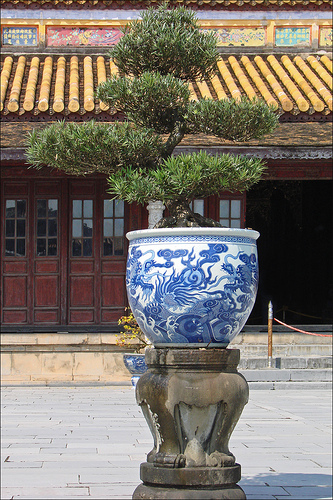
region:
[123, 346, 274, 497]
weathered and chipped pedestal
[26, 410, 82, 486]
staggered brick walk way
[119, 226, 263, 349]
blue and white flower planter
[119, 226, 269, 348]
flower planter with Asian motif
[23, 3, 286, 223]
bonsai plant in a planter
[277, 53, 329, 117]
bamboo sticks on the roof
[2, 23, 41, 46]
blue and gold decoration on roof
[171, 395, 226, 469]
chipped off portion of pedastal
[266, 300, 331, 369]
velvet rope and stand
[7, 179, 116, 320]
sliding wooden walls with many windows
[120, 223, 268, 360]
A blue and white vase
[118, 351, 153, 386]
A blue and white vase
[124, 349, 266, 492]
A stone stand for the vase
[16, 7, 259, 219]
a bonsai tree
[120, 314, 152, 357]
A plant in the vase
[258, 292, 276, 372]
A wooden rod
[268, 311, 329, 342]
A velvet rope blocking entrance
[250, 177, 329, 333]
The entrance to an oriental building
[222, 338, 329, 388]
A small set of stairs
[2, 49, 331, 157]
the roof of the oriental building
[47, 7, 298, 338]
a plant in a pot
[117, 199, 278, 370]
a blue planters pot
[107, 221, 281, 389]
a white planters pot with blue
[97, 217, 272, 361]
blue painted on to the pot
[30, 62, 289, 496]
planter pot on a statue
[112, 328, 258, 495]
cement statue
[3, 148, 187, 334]
doors to a building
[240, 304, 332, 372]
cement stairs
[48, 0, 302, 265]
a plant with green leaves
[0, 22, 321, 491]
potted plant in front of a Chinese building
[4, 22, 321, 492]
potted plant in front of an asian building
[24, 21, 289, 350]
tree in a white and blue planter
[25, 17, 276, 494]
potted plant on a pedestal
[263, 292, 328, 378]
roped off entrance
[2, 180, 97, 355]
red french doors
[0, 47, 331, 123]
bamboo on a roof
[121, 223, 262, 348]
white and blue china planter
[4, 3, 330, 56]
decorative Chinese on a building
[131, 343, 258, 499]
cement pedestal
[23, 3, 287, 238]
old evergreen bonsai tree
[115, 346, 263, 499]
concrete plant pot base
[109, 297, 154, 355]
yellow flowering tree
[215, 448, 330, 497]
shadow from tree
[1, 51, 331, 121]
yellow asian style roof top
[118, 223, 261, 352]
white ceramic pot with blue dragon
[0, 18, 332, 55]
beautiful hand painted art work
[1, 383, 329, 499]
grey stone slab outdoor flooring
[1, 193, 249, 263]
paned glass windows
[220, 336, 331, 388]
small grey stone stair case